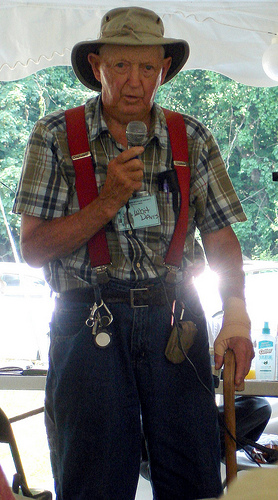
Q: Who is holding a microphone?
A: Old man.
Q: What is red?
A: Suspenders.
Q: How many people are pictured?
A: One.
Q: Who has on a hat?
A: The man.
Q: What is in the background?
A: Trees.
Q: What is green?
A: The trees.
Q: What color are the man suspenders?
A: Red.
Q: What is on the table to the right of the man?
A: Mosquito spray.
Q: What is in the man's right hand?
A: A walking cane.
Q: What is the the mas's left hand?
A: A microphone.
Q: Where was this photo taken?
A: In the woods.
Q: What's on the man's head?
A: A hat.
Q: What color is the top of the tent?
A: White.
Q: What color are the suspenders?
A: Red.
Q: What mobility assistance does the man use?
A: Cane.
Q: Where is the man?
A: Under a tent.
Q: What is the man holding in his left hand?
A: A cane.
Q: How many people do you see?
A: One.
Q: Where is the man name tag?
A: Around his neck.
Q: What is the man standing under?
A: Tent.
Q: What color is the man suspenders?
A: Red.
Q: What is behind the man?
A: Table.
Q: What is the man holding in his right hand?
A: Microphone.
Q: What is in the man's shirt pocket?
A: Pen,eyeglasses case.